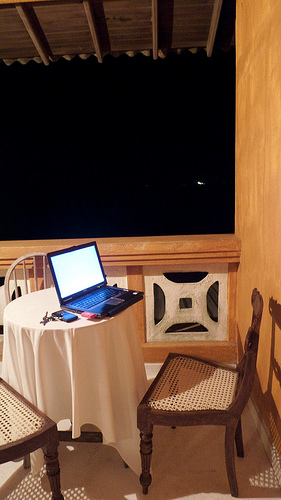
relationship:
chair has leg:
[137, 279, 272, 495] [225, 427, 236, 498]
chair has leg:
[137, 279, 272, 495] [237, 433, 247, 464]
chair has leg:
[137, 279, 272, 495] [143, 384, 151, 435]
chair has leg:
[137, 287, 264, 498] [44, 446, 69, 497]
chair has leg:
[137, 279, 272, 495] [26, 461, 34, 471]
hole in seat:
[151, 397, 159, 409] [146, 355, 238, 414]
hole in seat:
[6, 410, 16, 422] [1, 387, 41, 436]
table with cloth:
[19, 299, 34, 324] [22, 339, 118, 402]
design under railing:
[141, 270, 227, 340] [110, 240, 242, 261]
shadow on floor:
[82, 459, 114, 494] [165, 451, 220, 499]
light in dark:
[181, 169, 213, 194] [47, 87, 129, 124]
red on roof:
[115, 14, 127, 26] [6, 7, 222, 57]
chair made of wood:
[137, 279, 272, 495] [250, 321, 254, 344]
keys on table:
[39, 315, 51, 325] [19, 299, 34, 324]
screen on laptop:
[69, 268, 82, 273] [45, 243, 140, 320]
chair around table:
[137, 287, 264, 498] [19, 299, 34, 324]